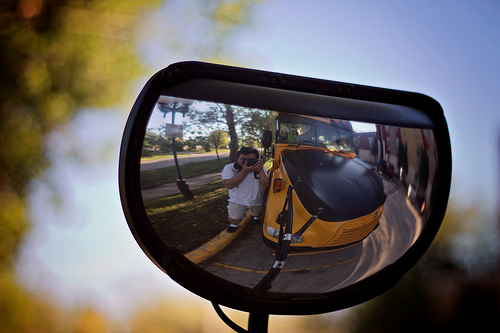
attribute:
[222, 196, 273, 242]
cargo shorts — khaki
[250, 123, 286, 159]
black mirror — silver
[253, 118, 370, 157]
windshield of bus — glass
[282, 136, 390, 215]
hood of bus — black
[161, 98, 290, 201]
trees near building — green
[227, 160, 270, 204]
shirt — white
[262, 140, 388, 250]
bus — yellow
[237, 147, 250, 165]
hair — black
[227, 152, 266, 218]
shirt — white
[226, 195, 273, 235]
shorts — tan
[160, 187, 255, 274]
concrete — yellow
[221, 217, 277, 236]
shoes — black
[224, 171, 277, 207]
shirt — white